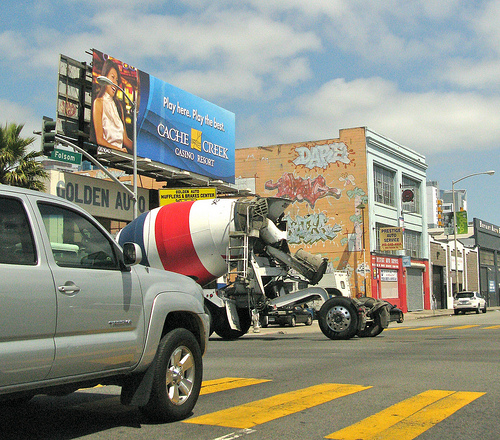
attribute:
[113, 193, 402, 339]
concrete mixer — red white, blue, large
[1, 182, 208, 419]
truck — silver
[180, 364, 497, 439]
crosswalk — yellow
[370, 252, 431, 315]
storefront — red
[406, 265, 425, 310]
rollup door — grey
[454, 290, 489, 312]
car — white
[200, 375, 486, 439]
yellow lines — thick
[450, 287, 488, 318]
van — white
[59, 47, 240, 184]
billboard — blue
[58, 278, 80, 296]
handle — grey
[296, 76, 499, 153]
clouds — fluffy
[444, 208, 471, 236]
sign — green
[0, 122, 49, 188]
tree — green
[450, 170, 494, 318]
street light — tall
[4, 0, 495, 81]
sky — blue